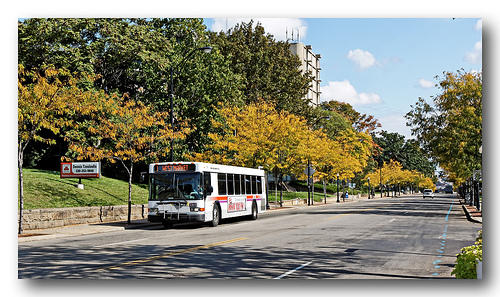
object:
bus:
[141, 160, 267, 228]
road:
[21, 204, 463, 280]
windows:
[217, 172, 227, 195]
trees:
[253, 108, 311, 207]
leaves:
[154, 85, 170, 94]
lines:
[95, 234, 250, 273]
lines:
[443, 206, 453, 224]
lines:
[269, 258, 319, 280]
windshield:
[150, 172, 204, 199]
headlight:
[190, 206, 203, 212]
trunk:
[126, 163, 133, 224]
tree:
[61, 90, 195, 226]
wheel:
[206, 203, 220, 227]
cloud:
[347, 48, 378, 71]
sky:
[286, 17, 481, 134]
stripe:
[386, 215, 398, 224]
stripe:
[333, 212, 355, 217]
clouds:
[319, 78, 383, 106]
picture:
[18, 18, 483, 279]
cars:
[420, 187, 434, 198]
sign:
[59, 161, 101, 178]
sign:
[303, 166, 318, 175]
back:
[303, 164, 317, 207]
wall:
[28, 208, 120, 220]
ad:
[227, 196, 247, 211]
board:
[153, 163, 191, 172]